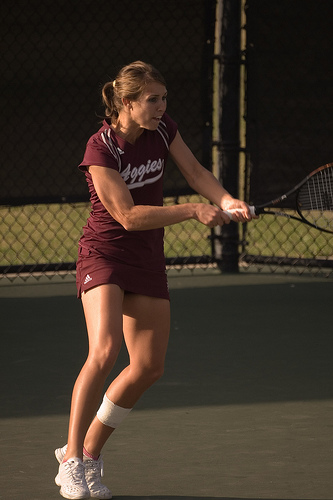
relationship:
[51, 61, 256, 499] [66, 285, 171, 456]
woman has legs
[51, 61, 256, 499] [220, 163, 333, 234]
woman holding tennis racket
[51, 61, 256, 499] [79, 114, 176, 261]
woman wearing jersey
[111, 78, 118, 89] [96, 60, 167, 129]
tie in hair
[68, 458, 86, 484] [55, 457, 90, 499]
laces on shoe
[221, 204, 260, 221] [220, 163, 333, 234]
handle on tennis racket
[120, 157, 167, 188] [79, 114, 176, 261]
lettering on jersey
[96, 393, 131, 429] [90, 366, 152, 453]
bandage on calf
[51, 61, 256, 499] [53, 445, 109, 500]
woman wearing shoes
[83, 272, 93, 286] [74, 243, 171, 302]
logo on skirt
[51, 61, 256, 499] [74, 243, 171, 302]
woman wearing skirt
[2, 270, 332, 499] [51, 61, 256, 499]
ground under woman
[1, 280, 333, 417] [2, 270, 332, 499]
shadow on ground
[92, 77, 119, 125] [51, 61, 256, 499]
ponytail on woman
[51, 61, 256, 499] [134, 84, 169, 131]
woman has face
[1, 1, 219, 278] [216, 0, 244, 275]
fence next to pole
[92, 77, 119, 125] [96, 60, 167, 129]
ponytail in hair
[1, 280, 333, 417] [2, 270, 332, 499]
shadow casted on ground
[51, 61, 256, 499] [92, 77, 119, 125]
woman has ponytail